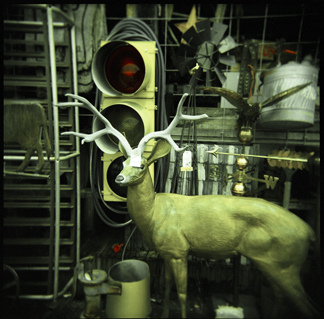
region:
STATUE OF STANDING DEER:
[58, 81, 319, 316]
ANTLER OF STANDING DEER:
[60, 85, 133, 156]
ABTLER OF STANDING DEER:
[140, 91, 209, 172]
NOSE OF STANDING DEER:
[115, 173, 124, 180]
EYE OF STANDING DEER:
[121, 160, 127, 165]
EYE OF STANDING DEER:
[131, 163, 144, 171]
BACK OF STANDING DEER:
[186, 195, 231, 212]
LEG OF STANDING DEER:
[169, 260, 189, 317]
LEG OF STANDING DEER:
[157, 264, 168, 317]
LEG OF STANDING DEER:
[270, 264, 320, 315]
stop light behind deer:
[91, 39, 154, 200]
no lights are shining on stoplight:
[91, 39, 154, 201]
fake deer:
[56, 92, 320, 317]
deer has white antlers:
[56, 93, 208, 156]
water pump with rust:
[78, 257, 120, 318]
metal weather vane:
[202, 82, 311, 306]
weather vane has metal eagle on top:
[199, 69, 318, 307]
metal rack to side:
[2, 0, 78, 315]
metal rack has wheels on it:
[1, 0, 77, 316]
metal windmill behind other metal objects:
[177, 20, 237, 89]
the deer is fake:
[56, 92, 315, 317]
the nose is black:
[116, 174, 124, 179]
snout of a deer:
[114, 174, 128, 184]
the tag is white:
[129, 152, 139, 167]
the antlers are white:
[53, 91, 207, 155]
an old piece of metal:
[77, 254, 120, 318]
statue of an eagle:
[202, 82, 309, 125]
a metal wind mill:
[178, 19, 237, 93]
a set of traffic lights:
[91, 39, 158, 200]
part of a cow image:
[5, 104, 51, 171]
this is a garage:
[12, 15, 292, 288]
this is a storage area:
[20, 78, 286, 305]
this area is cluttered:
[25, 74, 279, 266]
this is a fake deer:
[78, 103, 301, 302]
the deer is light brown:
[135, 182, 293, 291]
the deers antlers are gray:
[62, 77, 180, 158]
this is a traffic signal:
[87, 69, 183, 193]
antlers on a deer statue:
[54, 91, 206, 154]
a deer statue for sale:
[111, 129, 314, 312]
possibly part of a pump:
[61, 251, 119, 313]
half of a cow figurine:
[0, 97, 49, 169]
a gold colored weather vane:
[202, 125, 305, 191]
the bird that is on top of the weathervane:
[190, 78, 310, 147]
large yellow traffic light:
[89, 37, 152, 199]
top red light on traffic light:
[100, 41, 141, 89]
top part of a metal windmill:
[175, 16, 238, 86]